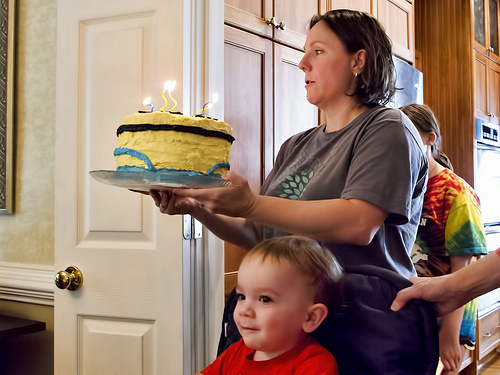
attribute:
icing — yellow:
[123, 103, 231, 177]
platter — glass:
[93, 161, 229, 206]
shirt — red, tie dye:
[208, 337, 330, 373]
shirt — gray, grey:
[271, 115, 436, 296]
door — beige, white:
[60, 16, 228, 371]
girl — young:
[409, 107, 480, 302]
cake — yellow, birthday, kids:
[120, 108, 239, 178]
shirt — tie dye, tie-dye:
[416, 161, 487, 292]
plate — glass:
[99, 162, 224, 217]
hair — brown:
[329, 9, 380, 107]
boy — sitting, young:
[210, 238, 350, 366]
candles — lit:
[133, 66, 260, 142]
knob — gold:
[45, 241, 94, 301]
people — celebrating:
[217, 6, 485, 367]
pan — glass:
[86, 153, 246, 193]